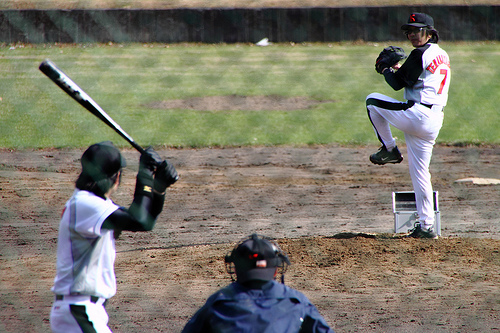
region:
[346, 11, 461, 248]
this is a person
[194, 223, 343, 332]
this is a person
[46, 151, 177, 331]
this is a person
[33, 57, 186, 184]
this is a bat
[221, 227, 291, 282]
this is a cape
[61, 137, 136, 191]
this is a cape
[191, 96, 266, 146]
a patch of green gras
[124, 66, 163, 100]
a patch of green grass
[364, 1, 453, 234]
person wearing black shoes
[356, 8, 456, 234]
person wearing black hat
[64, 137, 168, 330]
person wearing black hat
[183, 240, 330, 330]
person wearing black hat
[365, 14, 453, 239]
person wearing black glove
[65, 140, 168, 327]
person wearing black gloved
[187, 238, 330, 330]
person wearing blue shirt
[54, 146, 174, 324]
person wearing white shirt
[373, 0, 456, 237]
person wearing white shirt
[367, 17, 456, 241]
person wearing white pants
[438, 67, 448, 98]
a red number seven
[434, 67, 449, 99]
a red number seven on the shirt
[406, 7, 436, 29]
person wearing a black hat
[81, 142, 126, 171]
person wearing a black hat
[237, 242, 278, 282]
person wearing a black hat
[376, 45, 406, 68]
the pitcher's black glove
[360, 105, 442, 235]
pitcher wearing white pants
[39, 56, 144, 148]
baseball bat held by player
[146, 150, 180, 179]
player with black gloves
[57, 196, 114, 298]
player with white shirt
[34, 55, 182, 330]
batter waiting for pitched ball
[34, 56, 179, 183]
black baseball bat held by batter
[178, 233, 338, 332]
baseball catcher watching ball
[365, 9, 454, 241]
pitcher winding up to pitch ball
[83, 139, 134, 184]
black baseball cap on batter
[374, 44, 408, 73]
pitcher's baseball glove on hand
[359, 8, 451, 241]
baseball player number seven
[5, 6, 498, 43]
fence surrounding baseball field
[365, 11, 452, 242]
baseball player in white and black uniform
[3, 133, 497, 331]
dirt on baseball field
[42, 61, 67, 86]
a baseball bat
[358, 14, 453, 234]
the pitcher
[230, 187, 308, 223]
the dirt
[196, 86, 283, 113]
dirt in the grass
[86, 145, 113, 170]
a black hat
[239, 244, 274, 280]
the hat the catcher is wearing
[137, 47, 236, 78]
the grass in the outfield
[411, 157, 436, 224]
white pants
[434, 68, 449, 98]
number on the jersey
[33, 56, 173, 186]
black bat in a batter's hand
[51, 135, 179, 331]
man holding a bat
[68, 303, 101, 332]
black stripe on the batter's pants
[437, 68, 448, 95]
red number 7 on a shirt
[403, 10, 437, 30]
black baseball hat on the pitcher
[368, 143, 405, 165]
shoe raised in the air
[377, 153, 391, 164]
white nike swoosh on a shoe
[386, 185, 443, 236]
box on the mound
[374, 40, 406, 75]
dark baseball glove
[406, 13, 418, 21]
red symbol on a black hat